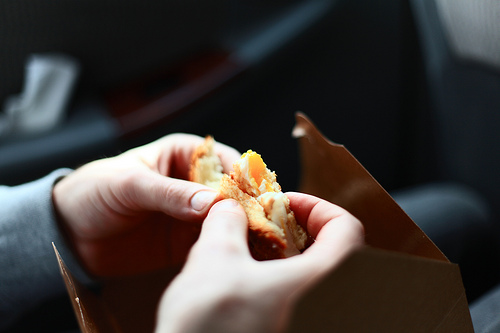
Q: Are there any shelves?
A: No, there are no shelves.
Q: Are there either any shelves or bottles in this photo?
A: No, there are no shelves or bottles.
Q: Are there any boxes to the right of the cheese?
A: Yes, there is a box to the right of the cheese.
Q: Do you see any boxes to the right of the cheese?
A: Yes, there is a box to the right of the cheese.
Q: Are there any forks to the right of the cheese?
A: No, there is a box to the right of the cheese.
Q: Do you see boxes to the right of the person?
A: Yes, there is a box to the right of the person.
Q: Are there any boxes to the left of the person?
A: No, the box is to the right of the person.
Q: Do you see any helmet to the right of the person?
A: No, there is a box to the right of the person.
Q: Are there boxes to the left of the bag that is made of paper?
A: Yes, there is a box to the left of the bag.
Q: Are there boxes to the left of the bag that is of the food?
A: Yes, there is a box to the left of the bag.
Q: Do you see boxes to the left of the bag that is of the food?
A: Yes, there is a box to the left of the bag.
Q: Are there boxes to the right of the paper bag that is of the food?
A: No, the box is to the left of the bag.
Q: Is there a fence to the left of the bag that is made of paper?
A: No, there is a box to the left of the bag.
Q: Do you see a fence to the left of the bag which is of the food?
A: No, there is a box to the left of the bag.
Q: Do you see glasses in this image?
A: No, there are no glasses.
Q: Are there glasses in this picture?
A: No, there are no glasses.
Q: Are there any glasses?
A: No, there are no glasses.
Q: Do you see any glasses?
A: No, there are no glasses.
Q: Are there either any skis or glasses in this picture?
A: No, there are no glasses or skis.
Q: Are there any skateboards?
A: No, there are no skateboards.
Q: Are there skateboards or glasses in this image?
A: No, there are no skateboards or glasses.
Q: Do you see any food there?
A: Yes, there is food.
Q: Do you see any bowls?
A: No, there are no bowls.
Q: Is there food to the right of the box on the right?
A: No, the food is to the left of the box.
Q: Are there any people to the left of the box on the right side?
A: Yes, there is a person to the left of the box.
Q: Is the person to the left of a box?
A: Yes, the person is to the left of a box.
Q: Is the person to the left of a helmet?
A: No, the person is to the left of a box.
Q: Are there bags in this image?
A: Yes, there is a bag.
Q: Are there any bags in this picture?
A: Yes, there is a bag.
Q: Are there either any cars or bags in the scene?
A: Yes, there is a bag.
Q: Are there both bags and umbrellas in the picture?
A: No, there is a bag but no umbrellas.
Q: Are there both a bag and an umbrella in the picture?
A: No, there is a bag but no umbrellas.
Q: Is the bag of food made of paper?
A: Yes, the bag is made of paper.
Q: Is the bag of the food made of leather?
A: No, the bag is made of paper.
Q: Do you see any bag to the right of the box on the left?
A: Yes, there is a bag to the right of the box.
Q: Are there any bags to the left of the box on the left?
A: No, the bag is to the right of the box.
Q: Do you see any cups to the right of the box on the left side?
A: No, there is a bag to the right of the box.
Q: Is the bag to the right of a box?
A: Yes, the bag is to the right of a box.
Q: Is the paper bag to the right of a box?
A: Yes, the bag is to the right of a box.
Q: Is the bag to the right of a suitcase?
A: No, the bag is to the right of a box.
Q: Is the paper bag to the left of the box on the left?
A: No, the bag is to the right of the box.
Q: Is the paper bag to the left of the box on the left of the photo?
A: No, the bag is to the right of the box.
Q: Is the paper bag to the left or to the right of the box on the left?
A: The bag is to the right of the box.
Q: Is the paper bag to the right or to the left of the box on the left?
A: The bag is to the right of the box.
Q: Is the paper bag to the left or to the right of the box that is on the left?
A: The bag is to the right of the box.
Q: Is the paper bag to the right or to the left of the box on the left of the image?
A: The bag is to the right of the box.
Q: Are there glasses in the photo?
A: No, there are no glasses.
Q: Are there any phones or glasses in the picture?
A: No, there are no glasses or phones.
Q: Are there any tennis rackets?
A: No, there are no tennis rackets.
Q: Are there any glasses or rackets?
A: No, there are no rackets or glasses.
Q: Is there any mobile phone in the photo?
A: No, there are no cell phones.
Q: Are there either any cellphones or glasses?
A: No, there are no cellphones or glasses.